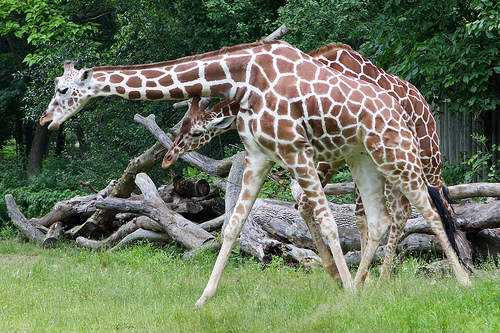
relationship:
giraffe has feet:
[38, 37, 477, 309] [187, 267, 478, 312]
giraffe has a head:
[38, 37, 477, 309] [37, 57, 92, 132]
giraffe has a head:
[164, 43, 477, 309] [161, 90, 221, 171]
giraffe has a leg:
[38, 37, 477, 309] [193, 156, 272, 311]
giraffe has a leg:
[38, 37, 477, 309] [279, 148, 358, 294]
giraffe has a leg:
[38, 37, 477, 309] [342, 149, 393, 291]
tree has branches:
[26, 5, 102, 181] [16, 22, 101, 66]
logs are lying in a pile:
[0, 105, 499, 273] [5, 93, 499, 275]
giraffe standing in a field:
[38, 37, 477, 309] [2, 139, 498, 332]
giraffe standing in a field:
[164, 43, 477, 309] [2, 139, 498, 332]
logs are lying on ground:
[0, 105, 499, 273] [4, 185, 498, 331]